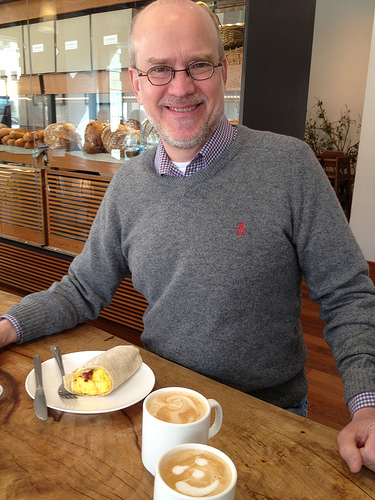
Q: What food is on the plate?
A: Egg burrito.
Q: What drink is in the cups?
A: Coffee.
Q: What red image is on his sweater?
A: Penguin.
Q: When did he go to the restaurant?
A: Morning.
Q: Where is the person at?
A: Restaurant.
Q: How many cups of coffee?
A: Two.